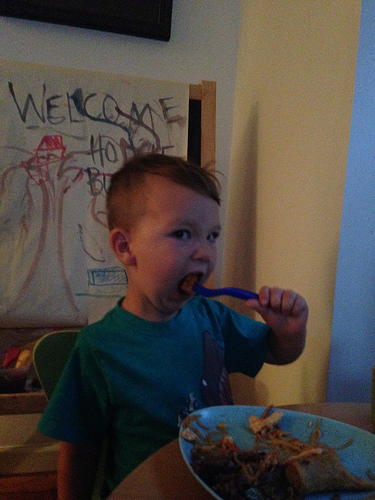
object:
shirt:
[34, 293, 269, 500]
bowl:
[176, 402, 374, 500]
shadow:
[218, 107, 269, 406]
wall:
[211, 0, 375, 408]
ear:
[108, 227, 137, 268]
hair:
[105, 154, 226, 243]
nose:
[192, 233, 213, 264]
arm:
[225, 308, 308, 366]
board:
[0, 59, 218, 416]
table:
[107, 399, 375, 500]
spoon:
[191, 281, 260, 302]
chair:
[31, 328, 110, 499]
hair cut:
[105, 151, 227, 232]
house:
[0, 0, 375, 499]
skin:
[137, 234, 158, 281]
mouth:
[176, 270, 204, 302]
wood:
[95, 395, 373, 497]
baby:
[32, 152, 309, 500]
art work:
[0, 67, 190, 329]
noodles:
[179, 404, 375, 500]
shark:
[198, 329, 232, 406]